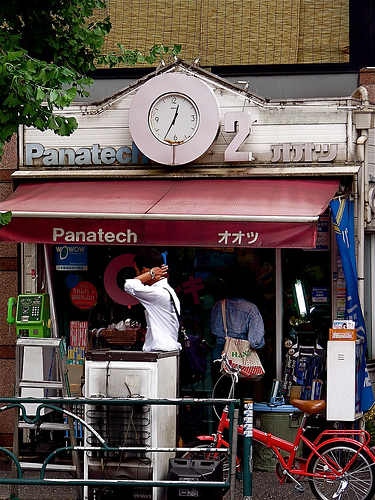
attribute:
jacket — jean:
[205, 296, 265, 358]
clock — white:
[127, 71, 221, 165]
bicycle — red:
[220, 335, 363, 491]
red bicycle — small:
[186, 348, 374, 498]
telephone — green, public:
[12, 290, 54, 348]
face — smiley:
[309, 136, 348, 168]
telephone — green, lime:
[4, 291, 52, 339]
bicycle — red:
[181, 377, 374, 495]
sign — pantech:
[21, 128, 150, 194]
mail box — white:
[326, 334, 361, 425]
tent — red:
[59, 193, 281, 241]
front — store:
[36, 86, 341, 413]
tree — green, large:
[2, 2, 193, 158]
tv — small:
[164, 452, 232, 497]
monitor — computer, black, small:
[170, 455, 223, 498]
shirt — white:
[128, 275, 183, 351]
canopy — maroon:
[0, 170, 356, 249]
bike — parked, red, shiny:
[188, 349, 373, 497]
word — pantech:
[47, 223, 141, 243]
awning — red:
[4, 177, 344, 249]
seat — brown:
[286, 394, 327, 414]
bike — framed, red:
[207, 385, 352, 492]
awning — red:
[150, 175, 300, 252]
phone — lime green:
[6, 292, 51, 338]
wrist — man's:
[144, 267, 164, 284]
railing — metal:
[4, 386, 265, 490]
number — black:
[171, 94, 181, 106]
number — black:
[184, 110, 198, 124]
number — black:
[166, 131, 183, 144]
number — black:
[146, 111, 160, 125]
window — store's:
[47, 242, 147, 351]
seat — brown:
[290, 398, 326, 415]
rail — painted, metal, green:
[5, 393, 244, 493]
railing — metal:
[6, 391, 245, 493]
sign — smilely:
[245, 228, 259, 244]